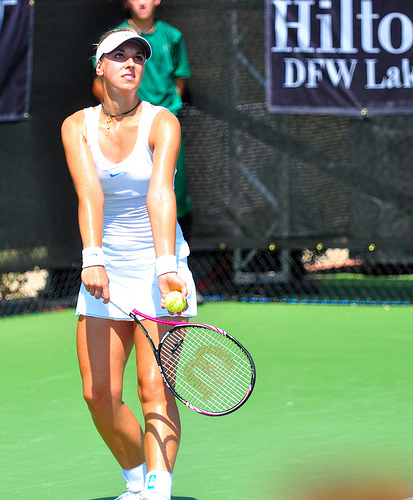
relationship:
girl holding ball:
[60, 48, 236, 392] [157, 281, 200, 318]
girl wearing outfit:
[60, 48, 236, 392] [79, 143, 168, 274]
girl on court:
[60, 48, 236, 392] [290, 307, 370, 417]